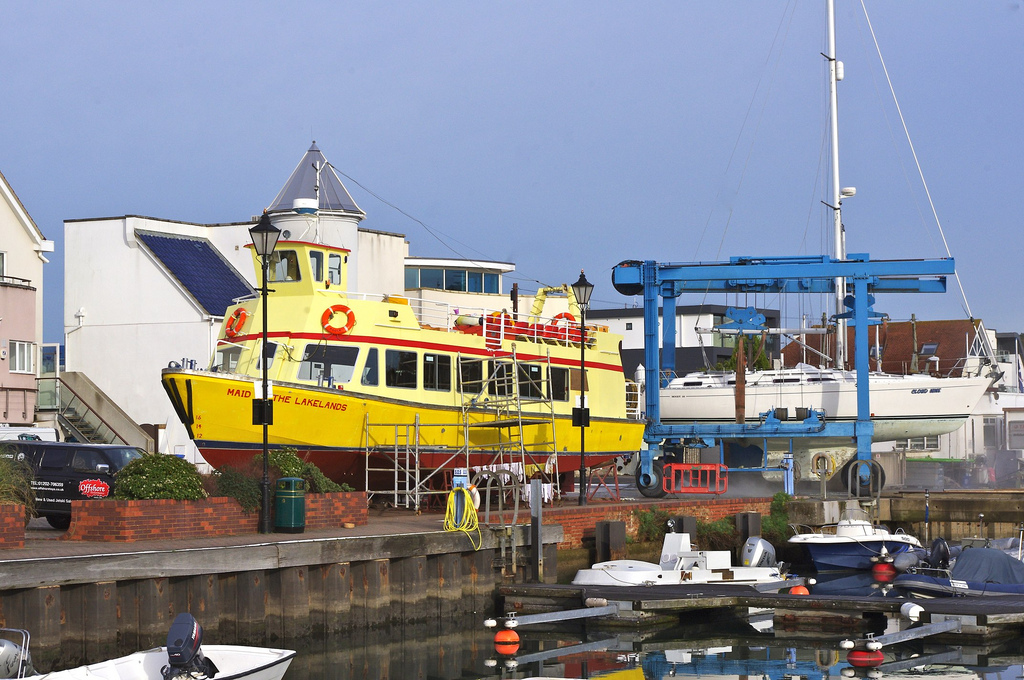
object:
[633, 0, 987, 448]
boat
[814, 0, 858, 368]
mast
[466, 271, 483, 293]
window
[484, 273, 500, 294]
window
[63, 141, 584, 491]
building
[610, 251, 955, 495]
structure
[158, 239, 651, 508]
ship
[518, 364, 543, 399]
window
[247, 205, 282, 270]
lamp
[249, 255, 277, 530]
post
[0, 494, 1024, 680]
land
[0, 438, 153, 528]
van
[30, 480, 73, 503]
text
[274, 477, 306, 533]
bin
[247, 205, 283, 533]
post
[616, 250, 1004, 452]
boat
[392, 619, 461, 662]
water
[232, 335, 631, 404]
stripe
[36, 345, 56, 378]
window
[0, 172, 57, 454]
building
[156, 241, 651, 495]
boat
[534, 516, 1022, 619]
boats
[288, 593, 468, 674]
water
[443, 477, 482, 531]
rope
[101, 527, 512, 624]
wall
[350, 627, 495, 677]
water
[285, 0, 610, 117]
sky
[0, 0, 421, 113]
sky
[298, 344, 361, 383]
window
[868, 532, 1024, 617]
boat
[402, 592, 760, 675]
water